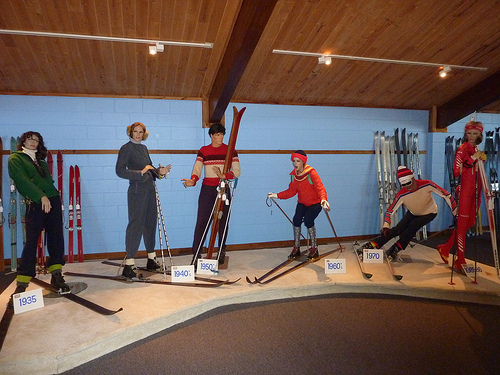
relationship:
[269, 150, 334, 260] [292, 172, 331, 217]
mannequin with jacket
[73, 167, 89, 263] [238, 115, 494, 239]
red ski on wall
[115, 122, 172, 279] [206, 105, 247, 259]
adult mannequin with skis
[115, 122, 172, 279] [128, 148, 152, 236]
adult mannequin wearing clothes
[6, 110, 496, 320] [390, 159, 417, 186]
mannequin wearing hat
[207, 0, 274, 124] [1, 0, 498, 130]
beam on ceiling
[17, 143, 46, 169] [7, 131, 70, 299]
turtle neck on adult mannequin